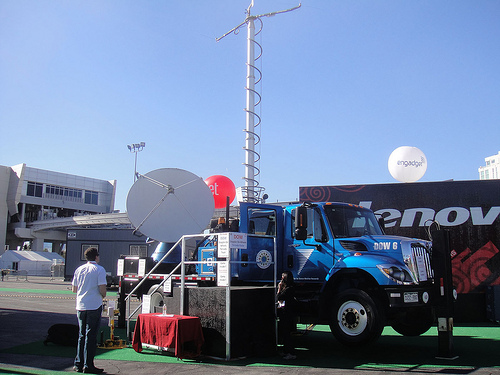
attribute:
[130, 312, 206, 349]
cloth — red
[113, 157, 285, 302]
dish — white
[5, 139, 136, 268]
building — white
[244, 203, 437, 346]
blue truck — big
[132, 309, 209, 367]
cloth — red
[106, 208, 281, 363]
staircase — portable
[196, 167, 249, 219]
balloon — red, large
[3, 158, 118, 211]
building — white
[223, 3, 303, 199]
pole — grey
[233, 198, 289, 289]
door — open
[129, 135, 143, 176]
lights — tall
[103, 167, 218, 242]
satellite — huge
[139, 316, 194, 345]
covering — red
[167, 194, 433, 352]
truck — tall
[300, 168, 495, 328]
board — black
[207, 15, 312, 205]
antennae — tall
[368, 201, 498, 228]
advertisement — big